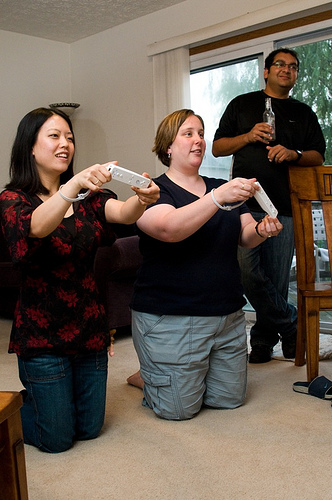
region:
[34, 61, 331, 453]
women on their knees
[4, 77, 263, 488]
two women on their knees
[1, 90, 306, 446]
two women kneeling on the carpet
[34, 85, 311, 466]
women kneeling on the carpet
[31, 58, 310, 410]
two women holding wii remotes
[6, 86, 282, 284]
women holding wii remotes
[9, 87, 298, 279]
women playing the wii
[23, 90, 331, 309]
two women playing the wii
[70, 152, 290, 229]
two white wii remotes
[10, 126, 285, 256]
two wii remotes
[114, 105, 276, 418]
a heavyset young lady on her knees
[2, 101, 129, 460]
an Asian girl on her knees playing a video game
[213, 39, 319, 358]
a young man in eyeglasses drinking a bottle of beer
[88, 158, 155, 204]
white video game controller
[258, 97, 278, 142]
glass beer bottle the man is holding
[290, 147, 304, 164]
black watch on the man's wrist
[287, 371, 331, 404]
black and grey sandal laying on the carpet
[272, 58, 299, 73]
eyeglasses the man is wearing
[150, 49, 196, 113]
white vertical blinds at the window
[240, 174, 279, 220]
white video game controller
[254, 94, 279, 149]
A hand holding a bottle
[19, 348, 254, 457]
Two pairs of knees kneeling on the floor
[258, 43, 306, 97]
A man with glasses smiling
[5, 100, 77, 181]
A woman with long hair smiling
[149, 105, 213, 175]
A woman with short hair smiling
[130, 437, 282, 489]
A beige floor rug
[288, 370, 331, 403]
One slipper on the floor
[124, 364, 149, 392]
A bare foot on the rug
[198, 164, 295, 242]
A pair of hands holding onto a wii controller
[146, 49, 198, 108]
White vertical blinds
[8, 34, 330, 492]
three people in a room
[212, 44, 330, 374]
man holding a bottle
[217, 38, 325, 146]
man wears glasses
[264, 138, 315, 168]
clock on a wrist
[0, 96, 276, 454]
two woman are kneeling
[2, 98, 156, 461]
woman holds a control game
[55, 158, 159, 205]
control game is white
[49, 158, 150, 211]
strap of control game in around wrist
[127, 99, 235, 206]
woman has short hair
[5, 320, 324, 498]
carpet on a room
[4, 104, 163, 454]
asian woman holding and playing wii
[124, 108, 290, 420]
blond woman kneeling playing and holding wii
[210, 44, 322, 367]
Indian man holding coke bottle, standing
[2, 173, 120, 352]
black shirt with red flowers on asian woman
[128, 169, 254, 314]
solid black shirt on blond woman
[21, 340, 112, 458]
jeans on asian woman who is kneeling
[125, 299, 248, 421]
gray cotton cargo pants on blond woman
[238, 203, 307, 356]
jeans on standing indian man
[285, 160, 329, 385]
tall wooden chair with carvings and open back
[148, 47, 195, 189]
white curtains that are open at window